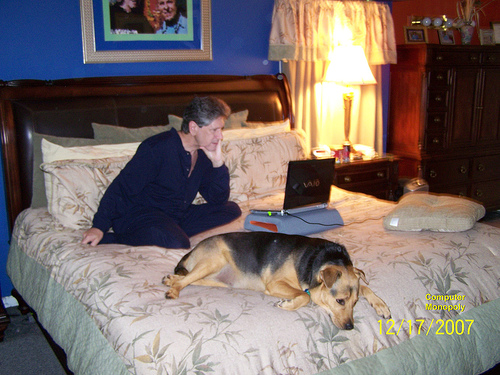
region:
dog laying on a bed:
[157, 233, 397, 335]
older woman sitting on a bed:
[65, 93, 266, 257]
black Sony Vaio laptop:
[248, 154, 343, 219]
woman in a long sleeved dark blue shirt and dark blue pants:
[85, 90, 246, 261]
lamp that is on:
[316, 45, 391, 163]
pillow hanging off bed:
[386, 181, 487, 243]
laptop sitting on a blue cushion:
[245, 153, 350, 240]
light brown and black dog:
[155, 223, 402, 338]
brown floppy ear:
[318, 263, 342, 290]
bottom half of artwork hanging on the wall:
[78, 2, 220, 63]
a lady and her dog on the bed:
[76, 85, 389, 334]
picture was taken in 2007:
[365, 284, 481, 351]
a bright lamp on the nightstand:
[309, 23, 391, 182]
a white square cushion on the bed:
[377, 183, 498, 249]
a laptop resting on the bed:
[241, 149, 351, 236]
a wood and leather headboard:
[2, 63, 305, 197]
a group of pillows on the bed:
[21, 104, 333, 209]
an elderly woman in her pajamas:
[72, 93, 259, 263]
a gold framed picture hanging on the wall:
[69, 4, 256, 63]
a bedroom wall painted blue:
[5, 5, 301, 322]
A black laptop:
[247, 159, 335, 216]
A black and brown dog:
[158, 230, 395, 327]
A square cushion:
[387, 175, 490, 234]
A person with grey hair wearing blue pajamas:
[83, 95, 243, 251]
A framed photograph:
[78, 0, 213, 63]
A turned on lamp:
[314, 33, 376, 160]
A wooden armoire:
[391, 42, 499, 210]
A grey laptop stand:
[243, 207, 345, 233]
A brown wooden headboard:
[0, 77, 288, 107]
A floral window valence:
[264, 0, 398, 62]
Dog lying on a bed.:
[161, 225, 394, 342]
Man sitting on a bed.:
[64, 93, 274, 238]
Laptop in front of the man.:
[241, 148, 344, 213]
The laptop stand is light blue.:
[241, 202, 352, 238]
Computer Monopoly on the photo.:
[411, 286, 473, 316]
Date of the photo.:
[368, 310, 488, 342]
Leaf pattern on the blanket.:
[130, 303, 352, 371]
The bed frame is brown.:
[17, 86, 162, 117]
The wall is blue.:
[9, 7, 62, 53]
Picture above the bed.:
[79, 1, 224, 66]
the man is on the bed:
[90, 88, 240, 249]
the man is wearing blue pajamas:
[60, 90, 241, 250]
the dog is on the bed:
[157, 232, 395, 334]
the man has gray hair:
[166, 96, 226, 143]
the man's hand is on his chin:
[192, 138, 224, 168]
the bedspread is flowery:
[9, 199, 496, 371]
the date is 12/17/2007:
[376, 310, 481, 349]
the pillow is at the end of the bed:
[381, 180, 483, 238]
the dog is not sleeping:
[145, 227, 395, 342]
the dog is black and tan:
[157, 232, 392, 336]